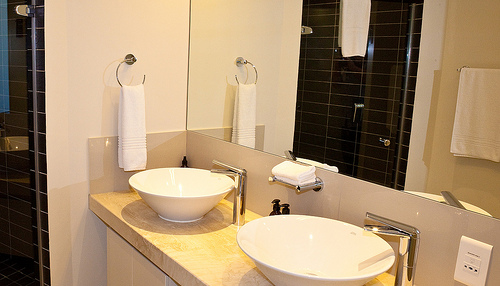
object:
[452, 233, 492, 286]
switch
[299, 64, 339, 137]
tiles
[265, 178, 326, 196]
shelf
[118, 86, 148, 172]
cloth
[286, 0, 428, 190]
door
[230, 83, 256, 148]
reflection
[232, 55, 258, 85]
silver hook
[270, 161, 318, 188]
soap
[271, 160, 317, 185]
towels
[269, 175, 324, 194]
soap holder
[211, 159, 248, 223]
faucet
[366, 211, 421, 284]
faucet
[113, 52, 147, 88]
rack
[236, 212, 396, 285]
sink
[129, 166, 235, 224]
sink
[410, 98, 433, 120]
ground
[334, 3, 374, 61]
towel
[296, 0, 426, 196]
glass door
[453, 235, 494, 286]
outlet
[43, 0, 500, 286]
wall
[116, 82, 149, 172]
two people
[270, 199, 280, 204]
top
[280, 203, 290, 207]
top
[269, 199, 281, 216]
bottle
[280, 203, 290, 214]
bottle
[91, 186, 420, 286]
countertop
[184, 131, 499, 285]
backsplash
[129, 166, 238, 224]
bowl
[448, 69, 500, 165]
towel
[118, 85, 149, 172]
towel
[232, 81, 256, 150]
towel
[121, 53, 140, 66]
ring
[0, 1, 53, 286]
tiles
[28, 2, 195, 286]
shower wall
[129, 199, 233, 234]
shadow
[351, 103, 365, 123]
hinge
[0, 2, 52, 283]
shower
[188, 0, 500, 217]
mirror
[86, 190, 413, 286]
counter